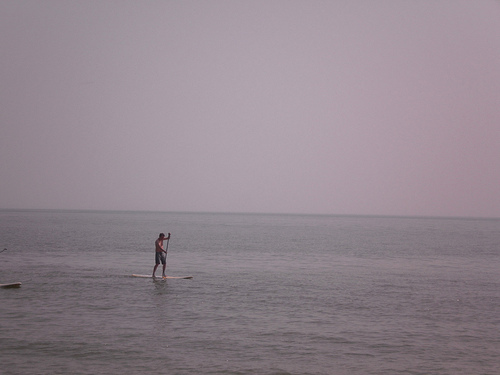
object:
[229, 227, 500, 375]
ocean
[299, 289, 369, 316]
waves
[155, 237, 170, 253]
shirt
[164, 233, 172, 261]
paddle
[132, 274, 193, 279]
board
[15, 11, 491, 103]
sky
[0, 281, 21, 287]
object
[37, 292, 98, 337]
water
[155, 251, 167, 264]
shorts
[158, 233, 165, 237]
hair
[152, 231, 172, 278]
male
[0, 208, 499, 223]
horizon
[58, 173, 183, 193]
distance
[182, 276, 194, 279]
front part